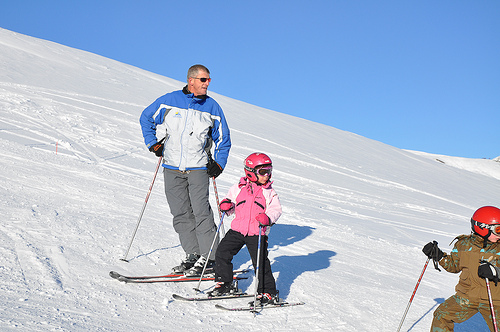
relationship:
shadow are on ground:
[228, 221, 313, 268] [4, 28, 498, 322]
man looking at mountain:
[137, 63, 233, 275] [1, 24, 497, 330]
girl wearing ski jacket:
[221, 153, 281, 305] [228, 176, 282, 234]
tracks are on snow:
[3, 81, 496, 243] [4, 28, 498, 322]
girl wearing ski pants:
[221, 153, 281, 305] [214, 230, 276, 296]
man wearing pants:
[137, 63, 233, 275] [162, 165, 220, 259]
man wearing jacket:
[137, 63, 233, 275] [139, 86, 233, 171]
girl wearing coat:
[221, 153, 281, 305] [228, 176, 282, 234]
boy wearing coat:
[422, 206, 499, 327] [436, 233, 499, 291]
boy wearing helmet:
[422, 206, 499, 327] [467, 203, 498, 244]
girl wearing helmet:
[221, 153, 281, 305] [242, 150, 271, 185]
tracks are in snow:
[3, 81, 496, 243] [4, 28, 498, 322]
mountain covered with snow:
[1, 24, 497, 330] [4, 28, 498, 322]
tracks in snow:
[3, 81, 496, 243] [4, 28, 498, 322]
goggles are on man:
[189, 75, 210, 86] [137, 63, 233, 275]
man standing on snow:
[137, 63, 233, 275] [4, 28, 498, 322]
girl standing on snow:
[221, 153, 281, 305] [4, 28, 498, 322]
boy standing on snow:
[422, 206, 499, 327] [4, 28, 498, 322]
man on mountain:
[137, 63, 233, 275] [1, 24, 497, 330]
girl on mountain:
[221, 153, 281, 305] [1, 24, 497, 330]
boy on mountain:
[422, 206, 499, 327] [1, 24, 497, 330]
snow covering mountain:
[4, 28, 498, 322] [1, 24, 497, 330]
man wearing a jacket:
[137, 63, 233, 275] [139, 86, 233, 171]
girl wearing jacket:
[221, 153, 281, 305] [228, 176, 282, 234]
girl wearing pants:
[221, 153, 281, 305] [214, 230, 276, 296]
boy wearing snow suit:
[422, 206, 499, 327] [430, 234, 498, 330]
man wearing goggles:
[137, 63, 233, 275] [189, 75, 210, 86]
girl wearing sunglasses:
[221, 153, 281, 305] [255, 166, 271, 176]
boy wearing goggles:
[422, 206, 499, 327] [486, 225, 499, 237]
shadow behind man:
[228, 221, 313, 268] [137, 63, 233, 275]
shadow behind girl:
[228, 247, 336, 305] [221, 153, 281, 305]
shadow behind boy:
[407, 294, 492, 327] [422, 206, 499, 327]